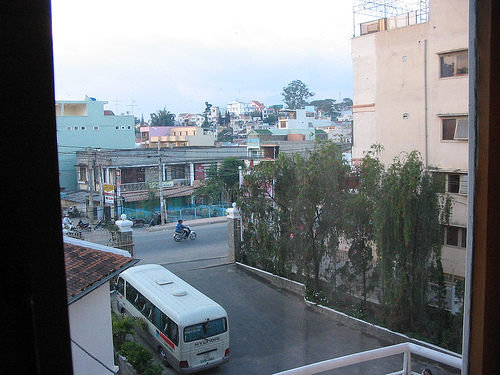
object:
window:
[439, 53, 454, 76]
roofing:
[64, 239, 132, 305]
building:
[62, 242, 142, 374]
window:
[308, 122, 315, 128]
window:
[115, 126, 118, 129]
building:
[56, 94, 137, 191]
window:
[78, 164, 88, 183]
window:
[455, 48, 470, 76]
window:
[447, 174, 462, 195]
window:
[445, 225, 458, 246]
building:
[75, 147, 247, 227]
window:
[93, 127, 98, 130]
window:
[453, 120, 470, 138]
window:
[280, 121, 287, 129]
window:
[458, 175, 469, 196]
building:
[351, 0, 469, 314]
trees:
[278, 79, 318, 110]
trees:
[112, 313, 143, 348]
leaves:
[407, 207, 416, 220]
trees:
[373, 150, 450, 332]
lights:
[179, 360, 191, 368]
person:
[175, 219, 191, 240]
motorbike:
[173, 226, 198, 243]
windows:
[182, 316, 229, 343]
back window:
[182, 316, 227, 342]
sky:
[50, 0, 428, 126]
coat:
[176, 222, 191, 229]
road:
[63, 218, 458, 374]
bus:
[113, 263, 231, 374]